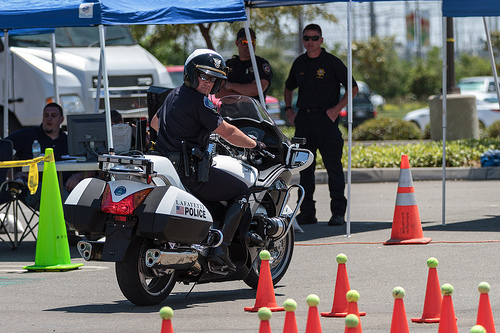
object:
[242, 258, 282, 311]
cone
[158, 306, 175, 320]
ball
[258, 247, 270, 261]
ball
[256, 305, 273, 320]
ball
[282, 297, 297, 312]
ball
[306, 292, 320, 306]
ball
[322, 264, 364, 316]
cone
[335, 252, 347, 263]
ball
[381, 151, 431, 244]
cone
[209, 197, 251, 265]
boots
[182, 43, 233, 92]
helmet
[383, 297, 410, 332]
cones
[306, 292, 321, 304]
balls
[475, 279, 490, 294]
balls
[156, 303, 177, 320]
balls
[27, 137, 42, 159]
bottle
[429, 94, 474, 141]
base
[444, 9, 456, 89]
pole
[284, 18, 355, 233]
officer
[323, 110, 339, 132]
pocket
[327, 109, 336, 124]
hand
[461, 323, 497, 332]
balls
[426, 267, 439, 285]
top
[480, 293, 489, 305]
top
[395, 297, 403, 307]
top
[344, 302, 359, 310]
top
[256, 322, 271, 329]
top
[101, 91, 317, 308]
motorcycle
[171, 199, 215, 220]
decal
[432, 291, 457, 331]
cone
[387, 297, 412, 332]
cone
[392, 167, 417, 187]
tape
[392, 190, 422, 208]
tape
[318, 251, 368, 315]
cone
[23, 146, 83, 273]
cone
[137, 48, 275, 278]
officer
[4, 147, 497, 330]
parking lot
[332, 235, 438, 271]
asphalt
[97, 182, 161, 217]
light